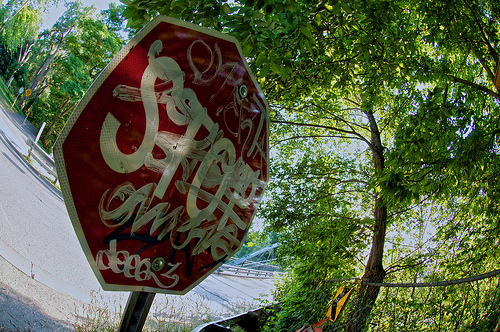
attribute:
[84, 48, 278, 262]
stop sign — vandilized, red, octagonal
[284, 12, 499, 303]
tree — tall, leaved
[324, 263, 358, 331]
sign — yellow, orange, curved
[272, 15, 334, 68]
leaves — green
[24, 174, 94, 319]
road — section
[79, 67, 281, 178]
sign — red, octagon, white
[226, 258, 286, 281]
bridge — section, narrow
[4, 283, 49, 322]
path — dirt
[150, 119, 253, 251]
graffiti — represented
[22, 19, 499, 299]
image — distorted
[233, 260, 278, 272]
guard rail — metal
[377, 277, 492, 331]
fence — metal, linked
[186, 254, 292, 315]
street — concrete, grey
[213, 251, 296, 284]
railing — metal, grey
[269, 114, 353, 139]
branch — thin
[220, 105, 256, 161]
tags — white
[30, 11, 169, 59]
day — sunny, beautiful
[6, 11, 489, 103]
trees — bloom